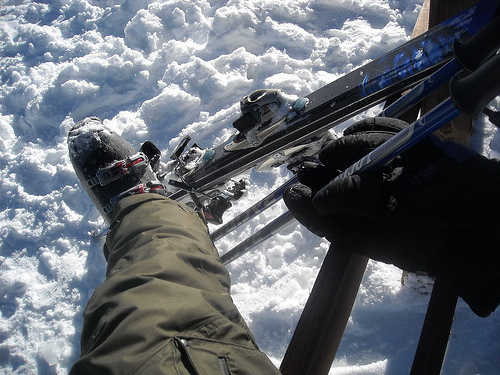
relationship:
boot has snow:
[60, 120, 162, 212] [64, 113, 111, 153]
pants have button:
[68, 192, 283, 374] [177, 336, 189, 349]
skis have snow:
[121, 11, 484, 261] [21, 14, 305, 151]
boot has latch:
[67, 121, 172, 238] [93, 148, 147, 183]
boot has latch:
[67, 121, 172, 238] [108, 175, 170, 208]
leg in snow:
[69, 131, 265, 371] [1, 13, 476, 350]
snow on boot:
[68, 22, 170, 102] [58, 109, 178, 225]